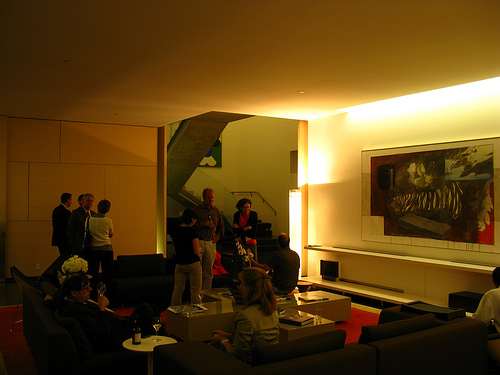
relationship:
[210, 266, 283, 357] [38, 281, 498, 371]
person sitting on chair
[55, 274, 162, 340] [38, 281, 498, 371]
man sitting on chair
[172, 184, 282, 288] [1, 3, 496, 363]
people in room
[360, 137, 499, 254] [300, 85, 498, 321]
picture in wall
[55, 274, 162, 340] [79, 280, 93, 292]
man wearing eyeglasses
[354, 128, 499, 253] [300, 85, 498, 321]
picture on wall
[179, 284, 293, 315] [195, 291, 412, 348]
book on table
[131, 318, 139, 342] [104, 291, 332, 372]
bottle on table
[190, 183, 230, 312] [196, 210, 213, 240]
man holding bottle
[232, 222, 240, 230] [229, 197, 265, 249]
lady has arm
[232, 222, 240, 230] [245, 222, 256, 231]
lady has arm